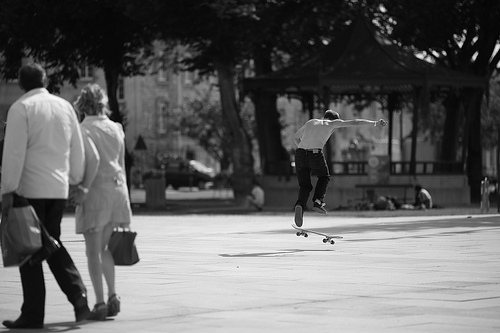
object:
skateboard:
[289, 221, 345, 244]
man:
[3, 62, 94, 330]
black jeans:
[291, 149, 330, 209]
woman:
[74, 81, 141, 317]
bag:
[109, 225, 141, 265]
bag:
[3, 205, 43, 267]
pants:
[10, 197, 89, 325]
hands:
[69, 188, 89, 206]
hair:
[17, 63, 45, 90]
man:
[289, 107, 388, 228]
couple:
[4, 62, 143, 329]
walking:
[3, 62, 139, 324]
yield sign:
[133, 133, 149, 150]